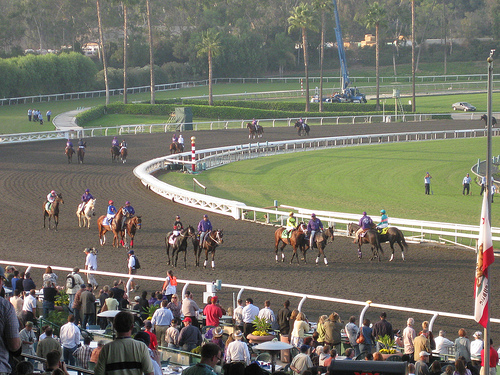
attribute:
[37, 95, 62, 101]
fence — white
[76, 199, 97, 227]
horse — white